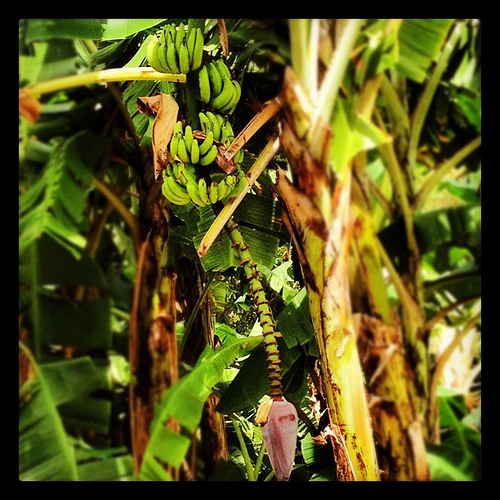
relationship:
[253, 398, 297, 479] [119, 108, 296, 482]
banana flower on tree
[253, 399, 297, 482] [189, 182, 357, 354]
banana flower on stem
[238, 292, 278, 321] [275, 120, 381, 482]
bug on tree stalk